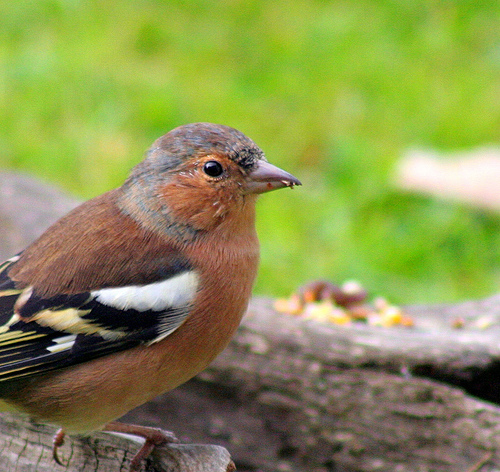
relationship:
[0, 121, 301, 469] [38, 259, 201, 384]
bird with wings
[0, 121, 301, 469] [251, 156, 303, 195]
bird has beak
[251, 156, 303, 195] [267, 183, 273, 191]
beak has blood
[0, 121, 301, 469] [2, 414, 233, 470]
bird perched on rock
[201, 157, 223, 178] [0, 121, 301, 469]
eye on bird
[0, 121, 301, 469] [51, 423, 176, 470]
bird has feet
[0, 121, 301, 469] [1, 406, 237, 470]
bird on bench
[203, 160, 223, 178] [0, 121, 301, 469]
eye of bird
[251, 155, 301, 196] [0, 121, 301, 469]
beak of bird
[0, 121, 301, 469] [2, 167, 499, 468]
bird sitting on a tree log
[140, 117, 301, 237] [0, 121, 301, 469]
head of a bird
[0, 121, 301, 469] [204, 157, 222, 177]
bird has an eye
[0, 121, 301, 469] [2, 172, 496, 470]
bird on a log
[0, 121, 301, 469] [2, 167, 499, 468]
bird standing on tree log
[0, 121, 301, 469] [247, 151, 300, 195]
bird with a beak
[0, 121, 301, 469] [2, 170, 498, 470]
bird sitting on a tree branch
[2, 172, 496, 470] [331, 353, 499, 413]
log with a hole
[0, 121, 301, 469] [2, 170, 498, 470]
bird perched on tree branch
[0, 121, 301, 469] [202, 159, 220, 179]
bird has eye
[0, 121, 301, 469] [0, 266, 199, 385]
bird has feathers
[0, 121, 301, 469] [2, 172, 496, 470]
bird on log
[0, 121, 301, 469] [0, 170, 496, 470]
bird on ledge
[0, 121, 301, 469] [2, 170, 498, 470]
bird on tree branch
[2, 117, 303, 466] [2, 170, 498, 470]
animal on tree branch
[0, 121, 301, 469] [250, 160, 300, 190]
bird has beak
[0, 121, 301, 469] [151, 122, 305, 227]
bird has head